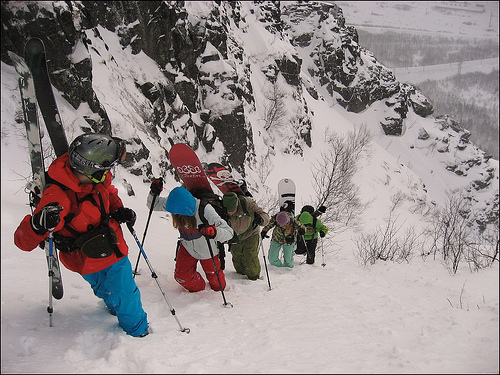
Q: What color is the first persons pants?
A: Blue.